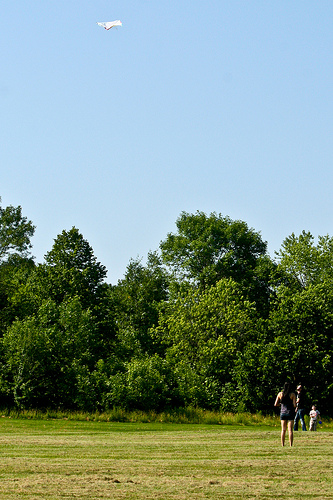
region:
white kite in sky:
[96, 17, 122, 30]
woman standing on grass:
[273, 381, 295, 448]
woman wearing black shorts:
[273, 381, 297, 446]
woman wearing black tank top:
[274, 381, 297, 447]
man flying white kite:
[295, 383, 306, 431]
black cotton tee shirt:
[296, 392, 304, 407]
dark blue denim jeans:
[294, 408, 306, 429]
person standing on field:
[309, 405, 321, 431]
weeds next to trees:
[1, 408, 278, 425]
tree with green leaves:
[4, 298, 97, 405]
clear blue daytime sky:
[1, 0, 331, 200]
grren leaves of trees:
[1, 207, 332, 411]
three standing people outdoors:
[274, 382, 320, 445]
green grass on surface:
[1, 417, 332, 499]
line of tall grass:
[0, 406, 275, 428]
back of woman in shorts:
[274, 381, 297, 447]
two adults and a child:
[273, 380, 322, 445]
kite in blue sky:
[89, 16, 135, 45]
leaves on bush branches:
[107, 355, 185, 409]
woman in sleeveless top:
[274, 379, 299, 445]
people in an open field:
[255, 371, 331, 453]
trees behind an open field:
[4, 198, 331, 491]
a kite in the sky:
[85, 6, 133, 45]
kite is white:
[88, 10, 130, 39]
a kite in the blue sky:
[9, 0, 258, 122]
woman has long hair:
[263, 375, 299, 451]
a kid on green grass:
[302, 397, 324, 437]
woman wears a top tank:
[269, 376, 301, 446]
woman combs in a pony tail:
[270, 374, 300, 450]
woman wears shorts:
[268, 370, 303, 455]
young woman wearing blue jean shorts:
[273, 382, 298, 447]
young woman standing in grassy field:
[273, 380, 298, 447]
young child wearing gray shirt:
[309, 404, 321, 431]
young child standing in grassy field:
[309, 403, 321, 430]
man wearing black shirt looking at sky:
[293, 383, 305, 430]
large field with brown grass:
[0, 421, 332, 497]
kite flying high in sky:
[95, 20, 122, 29]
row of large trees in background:
[2, 205, 331, 414]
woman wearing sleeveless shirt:
[272, 381, 295, 443]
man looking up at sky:
[294, 383, 307, 430]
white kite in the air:
[93, 13, 122, 34]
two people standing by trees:
[292, 383, 322, 436]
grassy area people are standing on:
[6, 413, 323, 499]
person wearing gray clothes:
[307, 404, 320, 431]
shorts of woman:
[277, 412, 292, 421]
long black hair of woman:
[278, 380, 288, 401]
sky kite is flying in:
[9, 7, 310, 245]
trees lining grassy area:
[0, 205, 329, 419]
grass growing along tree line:
[7, 405, 293, 425]